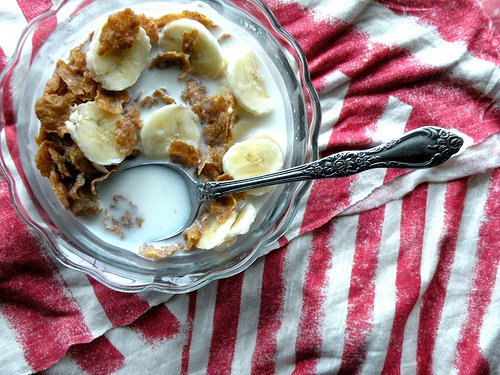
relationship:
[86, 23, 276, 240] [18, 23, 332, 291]
cereal inside bowl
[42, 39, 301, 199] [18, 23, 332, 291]
bananas inside bowl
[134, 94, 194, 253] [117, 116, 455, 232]
milk covers spoon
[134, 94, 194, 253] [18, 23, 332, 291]
milk inside bowl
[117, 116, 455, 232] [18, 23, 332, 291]
spoon inside bowl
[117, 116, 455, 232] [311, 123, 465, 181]
spoon has handle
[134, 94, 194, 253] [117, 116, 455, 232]
milk inside spoon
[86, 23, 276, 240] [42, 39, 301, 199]
cereal on bananas